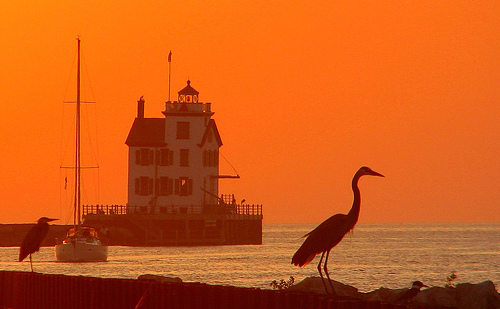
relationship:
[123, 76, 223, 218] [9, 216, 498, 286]
lighthouse on water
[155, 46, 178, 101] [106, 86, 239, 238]
flag pole on house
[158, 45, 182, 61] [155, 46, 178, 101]
flag on flag pole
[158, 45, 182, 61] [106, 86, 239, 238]
flag on house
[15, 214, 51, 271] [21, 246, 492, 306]
bird on seashore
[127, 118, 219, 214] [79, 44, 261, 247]
windows on lighthouse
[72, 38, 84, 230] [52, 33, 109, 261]
mast sails on boat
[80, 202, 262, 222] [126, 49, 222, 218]
fence around lighthouse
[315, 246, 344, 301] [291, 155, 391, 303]
legs of bird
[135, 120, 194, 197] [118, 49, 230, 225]
windows of building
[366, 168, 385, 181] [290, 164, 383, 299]
beak of bird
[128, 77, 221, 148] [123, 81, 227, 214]
top of house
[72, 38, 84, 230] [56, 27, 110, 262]
mast sails of boat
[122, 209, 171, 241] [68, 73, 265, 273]
stairs leading to house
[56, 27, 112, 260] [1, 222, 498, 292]
boat in water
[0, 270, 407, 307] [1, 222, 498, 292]
fence before water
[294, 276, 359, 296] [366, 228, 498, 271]
rock next to water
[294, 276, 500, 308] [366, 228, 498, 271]
rock next to water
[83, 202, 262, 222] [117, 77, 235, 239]
fence surrounding house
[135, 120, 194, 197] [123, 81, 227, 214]
windows on side of house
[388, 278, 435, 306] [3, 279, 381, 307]
bird on fence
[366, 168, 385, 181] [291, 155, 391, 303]
beak on bird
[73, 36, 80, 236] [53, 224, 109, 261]
mast of sailboat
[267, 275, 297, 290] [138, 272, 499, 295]
plants growing among rocks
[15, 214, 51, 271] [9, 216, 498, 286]
bird near water